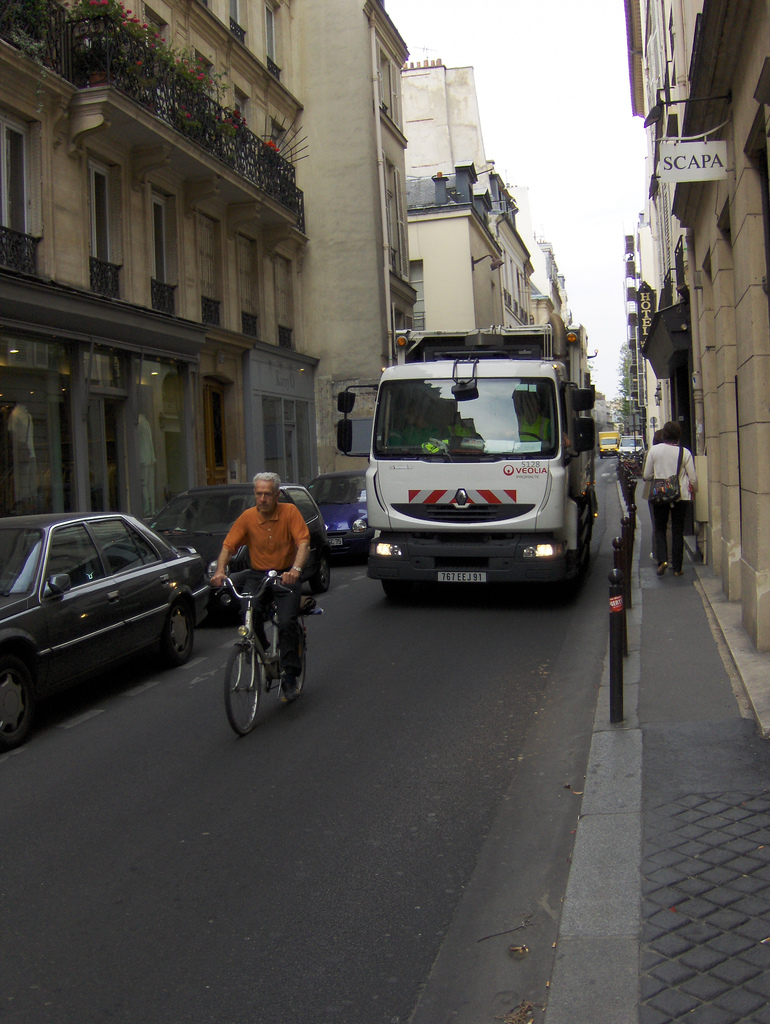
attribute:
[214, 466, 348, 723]
man — wearing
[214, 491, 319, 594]
shirt — orange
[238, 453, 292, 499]
hair — grey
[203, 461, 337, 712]
man — riding, grey haired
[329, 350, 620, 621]
truck — large, white, grey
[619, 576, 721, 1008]
sidewalk — brick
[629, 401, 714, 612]
woman — carrying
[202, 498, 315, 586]
shirt — orange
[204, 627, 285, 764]
wheel — black, bicycle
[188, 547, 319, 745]
bicycle — black, silver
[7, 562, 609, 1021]
road — paved, grey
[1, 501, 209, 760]
car — grey, four-door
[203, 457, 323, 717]
man — in orange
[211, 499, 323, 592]
shirt — orange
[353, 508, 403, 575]
headlight — on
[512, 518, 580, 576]
headlight — on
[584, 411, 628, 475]
truck — yellow, box, distant